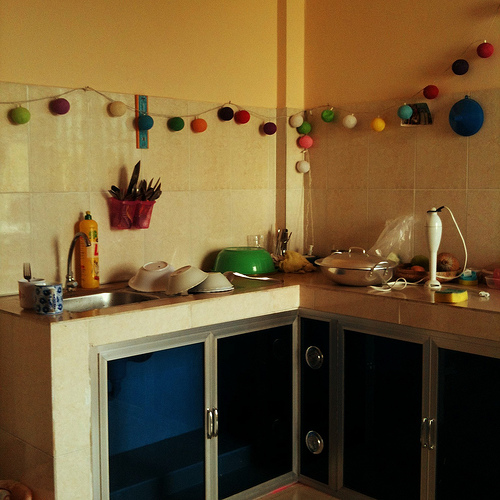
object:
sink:
[60, 285, 161, 314]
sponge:
[434, 286, 468, 303]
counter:
[32, 281, 305, 357]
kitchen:
[1, 0, 496, 498]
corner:
[25, 305, 70, 499]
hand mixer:
[424, 207, 446, 292]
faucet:
[70, 207, 105, 298]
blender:
[416, 197, 455, 303]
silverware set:
[109, 159, 160, 230]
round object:
[303, 342, 326, 373]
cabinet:
[96, 308, 300, 500]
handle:
[346, 247, 366, 258]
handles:
[203, 407, 217, 438]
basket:
[107, 201, 156, 230]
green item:
[215, 246, 276, 274]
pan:
[311, 244, 396, 285]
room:
[0, 3, 500, 500]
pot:
[314, 246, 397, 285]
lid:
[315, 246, 398, 268]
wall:
[1, 2, 303, 107]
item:
[165, 111, 187, 134]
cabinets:
[294, 321, 499, 498]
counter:
[287, 259, 499, 342]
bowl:
[128, 259, 176, 295]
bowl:
[164, 265, 208, 295]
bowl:
[194, 272, 232, 289]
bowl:
[212, 245, 277, 281]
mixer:
[424, 197, 446, 295]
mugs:
[35, 279, 63, 315]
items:
[46, 97, 73, 116]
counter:
[2, 250, 304, 331]